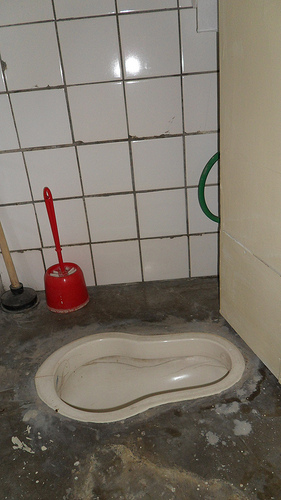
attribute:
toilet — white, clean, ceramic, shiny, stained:
[32, 329, 248, 424]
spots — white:
[5, 432, 46, 457]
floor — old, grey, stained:
[1, 280, 280, 499]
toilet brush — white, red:
[40, 186, 81, 281]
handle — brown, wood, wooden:
[1, 230, 24, 287]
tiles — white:
[1, 1, 217, 280]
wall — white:
[3, 0, 280, 305]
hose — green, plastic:
[198, 149, 229, 227]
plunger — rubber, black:
[1, 232, 43, 318]